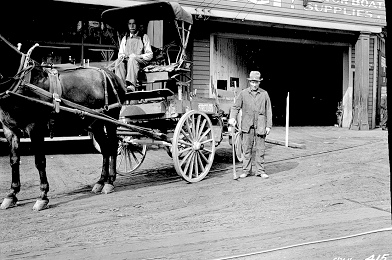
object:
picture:
[0, 0, 392, 260]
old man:
[227, 68, 274, 179]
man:
[110, 13, 156, 92]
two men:
[110, 13, 275, 180]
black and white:
[0, 0, 275, 213]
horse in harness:
[0, 36, 131, 211]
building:
[0, 0, 391, 131]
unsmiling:
[126, 14, 141, 35]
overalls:
[114, 30, 155, 89]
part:
[1, 23, 28, 83]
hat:
[246, 70, 264, 82]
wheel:
[87, 105, 149, 176]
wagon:
[87, 0, 244, 185]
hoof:
[88, 180, 115, 194]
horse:
[0, 61, 131, 212]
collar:
[129, 30, 139, 38]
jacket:
[228, 86, 274, 137]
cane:
[231, 124, 238, 180]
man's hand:
[227, 118, 237, 128]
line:
[211, 227, 392, 260]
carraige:
[97, 1, 218, 119]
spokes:
[197, 118, 208, 142]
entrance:
[209, 31, 357, 128]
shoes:
[126, 84, 135, 91]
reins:
[16, 69, 26, 79]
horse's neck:
[0, 35, 20, 100]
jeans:
[113, 54, 141, 87]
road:
[0, 130, 392, 233]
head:
[248, 70, 262, 91]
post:
[284, 91, 292, 147]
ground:
[0, 130, 386, 219]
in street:
[0, 128, 392, 259]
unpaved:
[209, 173, 311, 235]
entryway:
[206, 32, 356, 128]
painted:
[239, 0, 385, 20]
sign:
[133, 1, 388, 28]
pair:
[116, 30, 154, 62]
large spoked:
[171, 109, 218, 184]